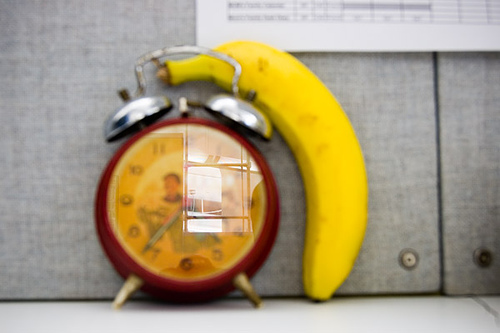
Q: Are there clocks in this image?
A: Yes, there is a clock.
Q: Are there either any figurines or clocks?
A: Yes, there is a clock.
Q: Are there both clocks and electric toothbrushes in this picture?
A: No, there is a clock but no electric toothbrushes.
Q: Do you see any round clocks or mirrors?
A: Yes, there is a round clock.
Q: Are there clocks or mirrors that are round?
A: Yes, the clock is round.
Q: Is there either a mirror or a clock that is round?
A: Yes, the clock is round.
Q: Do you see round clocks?
A: Yes, there is a round clock.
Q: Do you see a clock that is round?
A: Yes, there is a clock that is round.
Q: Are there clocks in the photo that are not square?
A: Yes, there is a round clock.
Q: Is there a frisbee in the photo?
A: No, there are no frisbees.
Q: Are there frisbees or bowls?
A: No, there are no frisbees or bowls.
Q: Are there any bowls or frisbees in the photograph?
A: No, there are no frisbees or bowls.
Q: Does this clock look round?
A: Yes, the clock is round.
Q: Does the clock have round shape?
A: Yes, the clock is round.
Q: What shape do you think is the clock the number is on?
A: The clock is round.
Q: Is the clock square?
A: No, the clock is round.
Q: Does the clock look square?
A: No, the clock is round.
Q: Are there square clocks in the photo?
A: No, there is a clock but it is round.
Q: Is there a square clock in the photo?
A: No, there is a clock but it is round.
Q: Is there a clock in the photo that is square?
A: No, there is a clock but it is round.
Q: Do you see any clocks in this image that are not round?
A: No, there is a clock but it is round.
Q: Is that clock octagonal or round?
A: The clock is round.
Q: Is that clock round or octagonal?
A: The clock is round.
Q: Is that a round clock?
A: Yes, that is a round clock.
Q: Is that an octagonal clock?
A: No, that is a round clock.